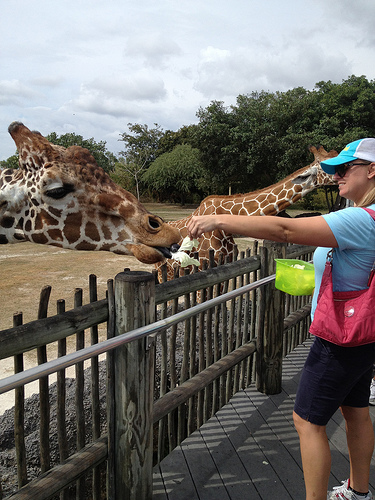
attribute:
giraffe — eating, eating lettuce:
[10, 122, 207, 284]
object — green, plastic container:
[260, 253, 325, 308]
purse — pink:
[317, 260, 371, 351]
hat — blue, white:
[319, 127, 374, 165]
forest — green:
[132, 128, 279, 179]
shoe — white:
[336, 471, 372, 496]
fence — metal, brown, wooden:
[58, 323, 178, 372]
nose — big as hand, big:
[141, 208, 188, 246]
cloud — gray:
[149, 29, 265, 102]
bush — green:
[147, 145, 217, 185]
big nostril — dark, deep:
[140, 215, 168, 234]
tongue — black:
[143, 236, 191, 265]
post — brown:
[85, 273, 203, 462]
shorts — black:
[302, 323, 369, 426]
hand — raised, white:
[175, 205, 220, 239]